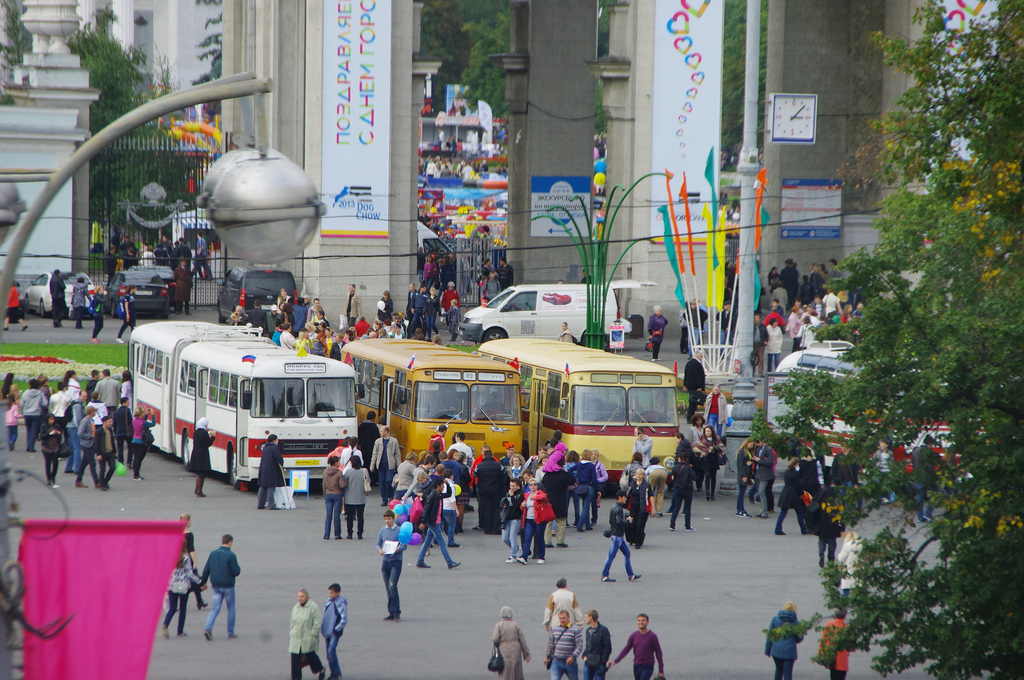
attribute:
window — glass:
[310, 375, 355, 413]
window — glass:
[247, 377, 306, 417]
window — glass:
[414, 381, 468, 423]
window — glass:
[460, 375, 512, 423]